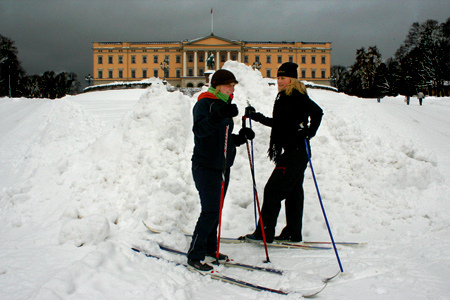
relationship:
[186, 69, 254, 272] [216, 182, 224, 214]
girl holding pole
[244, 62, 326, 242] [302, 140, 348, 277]
girl holding pole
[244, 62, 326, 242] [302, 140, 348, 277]
girl holding a pole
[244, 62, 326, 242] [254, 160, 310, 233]
girl wearing black pants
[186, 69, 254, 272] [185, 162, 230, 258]
girl wearing black pants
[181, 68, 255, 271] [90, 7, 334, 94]
girl in front of building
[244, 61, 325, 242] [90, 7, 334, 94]
girl in front of building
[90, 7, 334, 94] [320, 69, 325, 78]
building of many windows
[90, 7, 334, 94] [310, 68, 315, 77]
building of many windows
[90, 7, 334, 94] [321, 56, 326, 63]
building of many windows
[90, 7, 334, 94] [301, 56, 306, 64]
building of many windows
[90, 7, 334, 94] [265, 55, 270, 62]
building of many windows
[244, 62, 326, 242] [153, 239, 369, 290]
girl on skis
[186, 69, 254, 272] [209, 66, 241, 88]
girl has cap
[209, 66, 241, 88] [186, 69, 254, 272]
cap on girl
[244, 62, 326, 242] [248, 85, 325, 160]
girl in jacket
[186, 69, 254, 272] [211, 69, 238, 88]
girl wearing cap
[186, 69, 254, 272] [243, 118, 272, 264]
girl holding pole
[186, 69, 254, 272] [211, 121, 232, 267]
girl holding pole